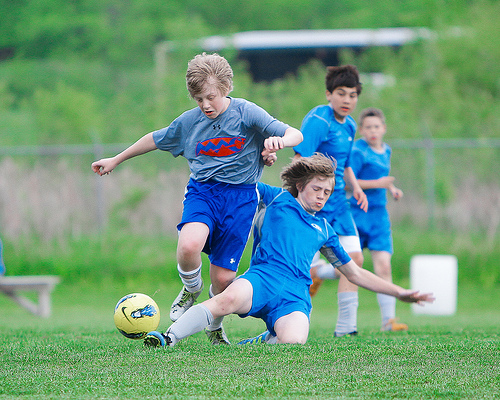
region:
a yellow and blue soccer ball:
[118, 292, 160, 339]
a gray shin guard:
[162, 305, 217, 341]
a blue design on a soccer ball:
[131, 302, 155, 320]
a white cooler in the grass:
[406, 247, 456, 318]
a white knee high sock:
[172, 261, 207, 298]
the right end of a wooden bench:
[1, 270, 63, 318]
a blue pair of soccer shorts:
[242, 267, 312, 328]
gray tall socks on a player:
[329, 288, 396, 334]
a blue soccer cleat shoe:
[139, 330, 172, 349]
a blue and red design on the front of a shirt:
[189, 129, 254, 161]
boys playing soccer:
[83, 35, 434, 359]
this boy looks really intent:
[160, 40, 252, 140]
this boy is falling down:
[121, 155, 452, 370]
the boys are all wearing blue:
[177, 117, 410, 362]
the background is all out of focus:
[71, 28, 481, 46]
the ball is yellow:
[104, 293, 166, 338]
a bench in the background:
[6, 263, 69, 325]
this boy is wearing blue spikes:
[130, 330, 280, 355]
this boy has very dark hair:
[314, 63, 366, 138]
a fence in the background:
[407, 126, 491, 234]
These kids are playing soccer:
[122, 63, 404, 346]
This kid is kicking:
[136, 270, 247, 356]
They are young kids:
[170, 28, 399, 298]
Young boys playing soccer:
[165, 50, 405, 255]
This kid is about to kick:
[154, 210, 209, 325]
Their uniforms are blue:
[170, 78, 395, 291]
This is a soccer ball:
[104, 290, 161, 342]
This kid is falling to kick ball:
[242, 147, 349, 328]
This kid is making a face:
[329, 73, 361, 118]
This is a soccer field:
[7, 267, 498, 393]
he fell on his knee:
[271, 310, 320, 357]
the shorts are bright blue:
[228, 201, 243, 225]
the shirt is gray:
[181, 126, 195, 136]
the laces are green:
[180, 289, 193, 302]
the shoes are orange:
[388, 319, 409, 337]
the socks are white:
[176, 314, 203, 331]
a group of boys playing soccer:
[79, 50, 437, 358]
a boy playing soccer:
[91, 49, 306, 331]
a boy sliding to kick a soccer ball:
[140, 154, 440, 363]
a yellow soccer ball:
[108, 290, 161, 341]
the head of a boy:
[174, 52, 234, 119]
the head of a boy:
[274, 150, 337, 218]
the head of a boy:
[318, 64, 364, 117]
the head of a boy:
[353, 107, 388, 147]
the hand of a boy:
[85, 154, 115, 179]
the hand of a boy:
[260, 134, 286, 154]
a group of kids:
[76, 9, 448, 351]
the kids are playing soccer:
[89, 29, 446, 353]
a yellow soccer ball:
[102, 288, 164, 340]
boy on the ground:
[139, 153, 439, 368]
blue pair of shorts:
[169, 168, 257, 276]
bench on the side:
[3, 257, 65, 323]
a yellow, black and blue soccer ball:
[113, 293, 162, 338]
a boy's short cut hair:
[180, 53, 239, 98]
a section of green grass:
[1, 323, 498, 399]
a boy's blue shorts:
[236, 264, 311, 329]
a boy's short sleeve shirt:
[155, 98, 290, 177]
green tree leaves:
[246, 60, 334, 128]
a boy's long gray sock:
[334, 288, 361, 333]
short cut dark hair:
[322, 61, 367, 95]